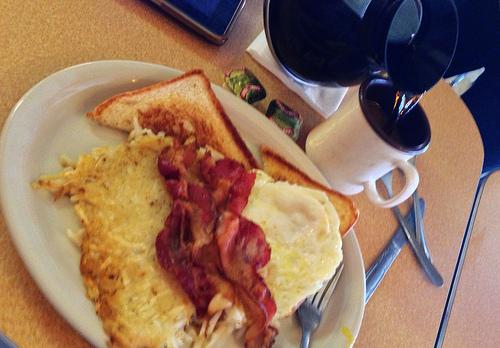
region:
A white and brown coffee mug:
[301, 68, 433, 210]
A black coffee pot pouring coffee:
[254, 0, 464, 125]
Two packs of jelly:
[208, 53, 305, 147]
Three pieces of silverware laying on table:
[365, 148, 450, 325]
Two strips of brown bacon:
[156, 137, 278, 346]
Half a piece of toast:
[86, 65, 255, 167]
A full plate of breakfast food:
[1, 58, 377, 347]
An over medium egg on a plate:
[241, 163, 346, 321]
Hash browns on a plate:
[31, 115, 180, 343]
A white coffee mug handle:
[362, 151, 425, 221]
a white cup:
[335, 111, 365, 158]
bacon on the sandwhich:
[161, 168, 256, 300]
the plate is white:
[18, 111, 65, 139]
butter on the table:
[220, 63, 268, 100]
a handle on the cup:
[392, 168, 417, 202]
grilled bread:
[151, 94, 209, 127]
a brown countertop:
[21, 15, 72, 54]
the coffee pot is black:
[280, 4, 378, 73]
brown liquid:
[390, 93, 410, 116]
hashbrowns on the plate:
[83, 168, 152, 231]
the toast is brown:
[164, 106, 199, 137]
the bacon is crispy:
[161, 145, 201, 247]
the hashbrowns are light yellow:
[111, 187, 149, 245]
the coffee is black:
[381, 103, 408, 129]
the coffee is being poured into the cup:
[386, 71, 425, 153]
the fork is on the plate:
[295, 274, 362, 343]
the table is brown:
[431, 124, 472, 175]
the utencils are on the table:
[367, 206, 443, 281]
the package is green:
[224, 68, 265, 93]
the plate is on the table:
[39, 51, 89, 90]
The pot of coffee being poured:
[259, 0, 461, 93]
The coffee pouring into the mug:
[389, 92, 428, 124]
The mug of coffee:
[303, 77, 433, 217]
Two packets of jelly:
[222, 61, 306, 144]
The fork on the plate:
[294, 258, 348, 346]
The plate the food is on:
[2, 57, 371, 346]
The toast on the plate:
[90, 65, 361, 238]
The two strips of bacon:
[151, 130, 281, 346]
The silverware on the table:
[364, 167, 447, 309]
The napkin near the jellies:
[244, 27, 348, 119]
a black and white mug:
[301, 68, 414, 229]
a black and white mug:
[319, 58, 495, 235]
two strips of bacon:
[155, 135, 264, 343]